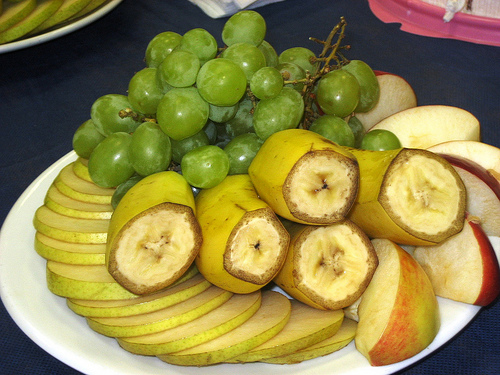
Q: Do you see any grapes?
A: Yes, there are grapes.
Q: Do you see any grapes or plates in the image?
A: Yes, there are grapes.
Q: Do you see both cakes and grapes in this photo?
A: No, there are grapes but no cakes.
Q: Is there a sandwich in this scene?
A: No, there are no sandwiches.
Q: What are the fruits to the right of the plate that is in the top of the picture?
A: The fruits are grapes.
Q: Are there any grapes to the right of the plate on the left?
A: Yes, there are grapes to the right of the plate.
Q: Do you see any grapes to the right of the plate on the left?
A: Yes, there are grapes to the right of the plate.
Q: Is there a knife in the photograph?
A: No, there are no knives.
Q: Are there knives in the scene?
A: No, there are no knives.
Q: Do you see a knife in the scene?
A: No, there are no knives.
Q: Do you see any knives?
A: No, there are no knives.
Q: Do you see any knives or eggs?
A: No, there are no knives or eggs.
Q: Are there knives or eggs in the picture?
A: No, there are no knives or eggs.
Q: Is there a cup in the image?
A: No, there are no cups.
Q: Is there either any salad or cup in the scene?
A: No, there are no cups or salad.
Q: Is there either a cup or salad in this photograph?
A: No, there are no cups or salad.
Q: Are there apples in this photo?
A: Yes, there are apples.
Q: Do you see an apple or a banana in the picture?
A: Yes, there are apples.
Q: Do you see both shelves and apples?
A: No, there are apples but no shelves.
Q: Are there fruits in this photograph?
A: Yes, there is a fruit.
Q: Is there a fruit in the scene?
A: Yes, there is a fruit.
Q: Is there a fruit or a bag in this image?
A: Yes, there is a fruit.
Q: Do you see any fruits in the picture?
A: Yes, there is a fruit.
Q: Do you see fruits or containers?
A: Yes, there is a fruit.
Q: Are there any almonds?
A: No, there are no almonds.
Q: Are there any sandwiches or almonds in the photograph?
A: No, there are no almonds or sandwiches.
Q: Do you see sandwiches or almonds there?
A: No, there are no almonds or sandwiches.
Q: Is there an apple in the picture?
A: Yes, there is an apple.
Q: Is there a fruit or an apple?
A: Yes, there is an apple.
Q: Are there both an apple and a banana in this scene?
A: Yes, there are both an apple and a banana.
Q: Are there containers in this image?
A: No, there are no containers.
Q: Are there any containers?
A: No, there are no containers.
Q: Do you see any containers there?
A: No, there are no containers.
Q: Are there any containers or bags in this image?
A: No, there are no containers or bags.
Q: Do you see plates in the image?
A: Yes, there is a plate.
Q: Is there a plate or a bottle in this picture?
A: Yes, there is a plate.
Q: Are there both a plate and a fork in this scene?
A: No, there is a plate but no forks.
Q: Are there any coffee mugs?
A: No, there are no coffee mugs.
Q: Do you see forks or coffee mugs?
A: No, there are no coffee mugs or forks.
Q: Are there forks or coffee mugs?
A: No, there are no coffee mugs or forks.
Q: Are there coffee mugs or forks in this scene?
A: No, there are no coffee mugs or forks.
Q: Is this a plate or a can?
A: This is a plate.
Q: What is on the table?
A: The plate is on the table.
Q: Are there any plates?
A: Yes, there is a plate.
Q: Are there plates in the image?
A: Yes, there is a plate.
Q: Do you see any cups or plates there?
A: Yes, there is a plate.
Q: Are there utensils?
A: No, there are no utensils.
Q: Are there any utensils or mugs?
A: No, there are no utensils or mugs.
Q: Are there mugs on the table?
A: No, there is a plate on the table.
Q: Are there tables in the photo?
A: Yes, there is a table.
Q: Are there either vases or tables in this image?
A: Yes, there is a table.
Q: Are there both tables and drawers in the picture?
A: No, there is a table but no drawers.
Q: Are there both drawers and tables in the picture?
A: No, there is a table but no drawers.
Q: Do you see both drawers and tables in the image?
A: No, there is a table but no drawers.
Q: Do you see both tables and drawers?
A: No, there is a table but no drawers.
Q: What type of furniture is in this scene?
A: The furniture is a table.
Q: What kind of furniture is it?
A: The piece of furniture is a table.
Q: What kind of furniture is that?
A: That is a table.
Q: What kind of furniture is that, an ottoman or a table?
A: That is a table.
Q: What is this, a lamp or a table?
A: This is a table.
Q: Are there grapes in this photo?
A: Yes, there are grapes.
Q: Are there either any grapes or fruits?
A: Yes, there are grapes.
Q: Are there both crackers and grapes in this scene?
A: No, there are grapes but no crackers.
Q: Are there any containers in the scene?
A: No, there are no containers.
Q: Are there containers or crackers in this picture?
A: No, there are no containers or crackers.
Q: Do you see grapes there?
A: Yes, there are grapes.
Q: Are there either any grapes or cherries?
A: Yes, there are grapes.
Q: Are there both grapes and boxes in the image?
A: No, there are grapes but no boxes.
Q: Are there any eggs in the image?
A: No, there are no eggs.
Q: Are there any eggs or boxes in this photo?
A: No, there are no eggs or boxes.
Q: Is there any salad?
A: No, there is no salad.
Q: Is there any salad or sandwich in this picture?
A: No, there are no salad or sandwiches.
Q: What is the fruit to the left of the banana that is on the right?
A: The fruit is a grape.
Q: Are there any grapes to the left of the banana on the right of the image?
A: Yes, there is a grape to the left of the banana.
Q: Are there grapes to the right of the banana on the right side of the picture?
A: No, the grape is to the left of the banana.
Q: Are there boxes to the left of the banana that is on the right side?
A: No, there is a grape to the left of the banana.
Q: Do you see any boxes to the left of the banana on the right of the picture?
A: No, there is a grape to the left of the banana.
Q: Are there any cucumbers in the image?
A: No, there are no cucumbers.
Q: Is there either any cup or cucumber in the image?
A: No, there are no cucumbers or cups.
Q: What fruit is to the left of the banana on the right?
A: The fruit is a grape.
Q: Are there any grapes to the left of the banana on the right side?
A: Yes, there is a grape to the left of the banana.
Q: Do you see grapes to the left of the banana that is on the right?
A: Yes, there is a grape to the left of the banana.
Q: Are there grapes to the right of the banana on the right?
A: No, the grape is to the left of the banana.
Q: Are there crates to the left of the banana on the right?
A: No, there is a grape to the left of the banana.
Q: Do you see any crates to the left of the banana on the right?
A: No, there is a grape to the left of the banana.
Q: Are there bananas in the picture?
A: Yes, there is a banana.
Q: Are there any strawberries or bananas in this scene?
A: Yes, there is a banana.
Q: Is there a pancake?
A: No, there are no pancakes.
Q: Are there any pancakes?
A: No, there are no pancakes.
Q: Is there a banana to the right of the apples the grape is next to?
A: Yes, there is a banana to the right of the apples.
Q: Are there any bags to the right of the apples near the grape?
A: No, there is a banana to the right of the apples.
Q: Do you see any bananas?
A: Yes, there is a banana.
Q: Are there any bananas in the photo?
A: Yes, there is a banana.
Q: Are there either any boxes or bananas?
A: Yes, there is a banana.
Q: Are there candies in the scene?
A: No, there are no candies.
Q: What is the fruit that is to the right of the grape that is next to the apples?
A: The fruit is a banana.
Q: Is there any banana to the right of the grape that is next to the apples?
A: Yes, there is a banana to the right of the grape.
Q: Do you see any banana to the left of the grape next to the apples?
A: No, the banana is to the right of the grape.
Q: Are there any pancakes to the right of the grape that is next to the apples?
A: No, there is a banana to the right of the grape.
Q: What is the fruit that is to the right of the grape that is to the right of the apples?
A: The fruit is a banana.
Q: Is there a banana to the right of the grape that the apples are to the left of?
A: Yes, there is a banana to the right of the grape.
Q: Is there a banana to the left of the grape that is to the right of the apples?
A: No, the banana is to the right of the grape.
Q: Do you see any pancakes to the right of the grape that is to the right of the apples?
A: No, there is a banana to the right of the grape.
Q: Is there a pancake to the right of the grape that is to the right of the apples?
A: No, there is a banana to the right of the grape.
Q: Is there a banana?
A: Yes, there is a banana.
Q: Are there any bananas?
A: Yes, there is a banana.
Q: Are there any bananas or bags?
A: Yes, there is a banana.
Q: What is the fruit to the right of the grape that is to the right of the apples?
A: The fruit is a banana.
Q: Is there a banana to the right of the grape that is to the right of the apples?
A: Yes, there is a banana to the right of the grape.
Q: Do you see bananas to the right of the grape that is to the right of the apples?
A: Yes, there is a banana to the right of the grape.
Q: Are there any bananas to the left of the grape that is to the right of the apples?
A: No, the banana is to the right of the grape.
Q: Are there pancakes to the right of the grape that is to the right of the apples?
A: No, there is a banana to the right of the grape.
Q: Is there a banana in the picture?
A: Yes, there is a banana.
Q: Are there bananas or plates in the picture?
A: Yes, there is a banana.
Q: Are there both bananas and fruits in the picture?
A: Yes, there are both a banana and a fruit.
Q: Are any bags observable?
A: No, there are no bags.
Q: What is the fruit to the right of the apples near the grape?
A: The fruit is a banana.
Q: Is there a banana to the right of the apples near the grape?
A: Yes, there is a banana to the right of the apples.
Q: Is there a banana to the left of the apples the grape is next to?
A: No, the banana is to the right of the apples.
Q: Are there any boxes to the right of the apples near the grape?
A: No, there is a banana to the right of the apples.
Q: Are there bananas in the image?
A: Yes, there is a banana.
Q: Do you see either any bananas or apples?
A: Yes, there is a banana.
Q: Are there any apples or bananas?
A: Yes, there is a banana.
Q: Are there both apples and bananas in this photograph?
A: Yes, there are both a banana and an apple.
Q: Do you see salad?
A: No, there is no salad.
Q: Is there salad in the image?
A: No, there is no salad.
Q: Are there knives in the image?
A: No, there are no knives.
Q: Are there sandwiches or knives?
A: No, there are no knives or sandwiches.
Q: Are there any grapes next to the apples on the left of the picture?
A: Yes, there is a grape next to the apples.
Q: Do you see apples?
A: Yes, there is an apple.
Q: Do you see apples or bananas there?
A: Yes, there is an apple.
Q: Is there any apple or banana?
A: Yes, there is an apple.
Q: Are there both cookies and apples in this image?
A: No, there is an apple but no cookies.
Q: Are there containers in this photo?
A: No, there are no containers.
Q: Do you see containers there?
A: No, there are no containers.